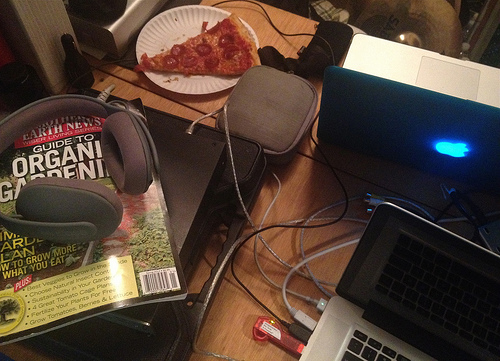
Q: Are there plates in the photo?
A: Yes, there is a plate.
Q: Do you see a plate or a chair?
A: Yes, there is a plate.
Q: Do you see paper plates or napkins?
A: Yes, there is a paper plate.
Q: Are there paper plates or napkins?
A: Yes, there is a paper plate.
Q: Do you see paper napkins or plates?
A: Yes, there is a paper plate.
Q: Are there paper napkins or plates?
A: Yes, there is a paper plate.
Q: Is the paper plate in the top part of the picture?
A: Yes, the plate is in the top of the image.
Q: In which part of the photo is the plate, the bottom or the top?
A: The plate is in the top of the image.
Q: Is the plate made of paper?
A: Yes, the plate is made of paper.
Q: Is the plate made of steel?
A: No, the plate is made of paper.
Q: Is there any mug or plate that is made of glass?
A: No, there is a plate but it is made of paper.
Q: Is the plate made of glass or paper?
A: The plate is made of paper.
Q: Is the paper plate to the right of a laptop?
A: No, the plate is to the left of a laptop.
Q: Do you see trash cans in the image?
A: No, there are no trash cans.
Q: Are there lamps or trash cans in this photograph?
A: No, there are no trash cans or lamps.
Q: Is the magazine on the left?
A: Yes, the magazine is on the left of the image.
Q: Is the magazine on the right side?
A: No, the magazine is on the left of the image.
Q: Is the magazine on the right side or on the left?
A: The magazine is on the left of the image.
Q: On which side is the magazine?
A: The magazine is on the left of the image.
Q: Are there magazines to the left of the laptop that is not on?
A: Yes, there is a magazine to the left of the laptop computer.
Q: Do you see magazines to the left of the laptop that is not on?
A: Yes, there is a magazine to the left of the laptop computer.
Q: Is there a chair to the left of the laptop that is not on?
A: No, there is a magazine to the left of the laptop.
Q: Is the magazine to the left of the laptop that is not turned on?
A: Yes, the magazine is to the left of the laptop.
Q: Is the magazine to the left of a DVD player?
A: No, the magazine is to the left of the laptop.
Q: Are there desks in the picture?
A: Yes, there is a desk.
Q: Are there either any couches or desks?
A: Yes, there is a desk.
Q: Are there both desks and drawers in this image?
A: No, there is a desk but no drawers.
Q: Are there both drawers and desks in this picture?
A: No, there is a desk but no drawers.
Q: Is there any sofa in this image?
A: No, there are no sofas.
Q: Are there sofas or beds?
A: No, there are no sofas or beds.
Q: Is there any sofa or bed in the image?
A: No, there are no sofas or beds.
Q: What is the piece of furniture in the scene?
A: The piece of furniture is a desk.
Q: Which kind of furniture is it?
A: The piece of furniture is a desk.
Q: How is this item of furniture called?
A: This is a desk.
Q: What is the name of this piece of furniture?
A: This is a desk.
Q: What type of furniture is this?
A: This is a desk.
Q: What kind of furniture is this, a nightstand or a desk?
A: This is a desk.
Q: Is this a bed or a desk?
A: This is a desk.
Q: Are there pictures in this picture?
A: No, there are no pictures.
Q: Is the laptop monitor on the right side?
A: Yes, the monitor is on the right of the image.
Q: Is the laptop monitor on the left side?
A: No, the monitor is on the right of the image.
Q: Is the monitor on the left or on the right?
A: The monitor is on the right of the image.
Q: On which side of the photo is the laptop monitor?
A: The monitor is on the right of the image.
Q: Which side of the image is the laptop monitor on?
A: The monitor is on the right of the image.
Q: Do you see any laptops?
A: Yes, there is a laptop.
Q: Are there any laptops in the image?
A: Yes, there is a laptop.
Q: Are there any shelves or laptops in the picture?
A: Yes, there is a laptop.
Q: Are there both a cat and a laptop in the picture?
A: No, there is a laptop but no cats.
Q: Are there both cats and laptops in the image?
A: No, there is a laptop but no cats.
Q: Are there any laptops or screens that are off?
A: Yes, the laptop is off.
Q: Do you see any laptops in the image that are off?
A: Yes, there is a laptop that is off.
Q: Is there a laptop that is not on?
A: Yes, there is a laptop that is off.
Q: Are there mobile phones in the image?
A: No, there are no mobile phones.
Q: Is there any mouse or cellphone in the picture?
A: No, there are no cell phones or computer mice.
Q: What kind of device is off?
A: The device is a laptop.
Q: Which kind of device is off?
A: The device is a laptop.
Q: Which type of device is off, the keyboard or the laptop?
A: The laptop is off.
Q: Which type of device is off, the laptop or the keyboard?
A: The laptop is off.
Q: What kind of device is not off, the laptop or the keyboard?
A: The keyboard is not off.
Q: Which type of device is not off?
A: The device is a keyboard.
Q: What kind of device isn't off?
A: The device is a keyboard.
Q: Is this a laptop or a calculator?
A: This is a laptop.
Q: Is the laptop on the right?
A: Yes, the laptop is on the right of the image.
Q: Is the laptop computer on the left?
A: No, the laptop computer is on the right of the image.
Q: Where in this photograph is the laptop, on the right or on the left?
A: The laptop is on the right of the image.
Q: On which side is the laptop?
A: The laptop is on the right of the image.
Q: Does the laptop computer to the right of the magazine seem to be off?
A: Yes, the laptop computer is off.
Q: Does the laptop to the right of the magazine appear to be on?
A: No, the laptop is off.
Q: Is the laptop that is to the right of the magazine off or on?
A: The laptop is off.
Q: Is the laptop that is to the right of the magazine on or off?
A: The laptop is off.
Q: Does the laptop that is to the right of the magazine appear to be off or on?
A: The laptop is off.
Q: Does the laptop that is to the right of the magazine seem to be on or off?
A: The laptop is off.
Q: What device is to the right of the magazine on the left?
A: The device is a laptop.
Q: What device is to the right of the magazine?
A: The device is a laptop.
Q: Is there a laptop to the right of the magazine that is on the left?
A: Yes, there is a laptop to the right of the magazine.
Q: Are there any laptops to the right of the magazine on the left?
A: Yes, there is a laptop to the right of the magazine.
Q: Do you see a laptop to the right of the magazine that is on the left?
A: Yes, there is a laptop to the right of the magazine.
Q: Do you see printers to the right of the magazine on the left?
A: No, there is a laptop to the right of the magazine.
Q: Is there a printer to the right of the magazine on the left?
A: No, there is a laptop to the right of the magazine.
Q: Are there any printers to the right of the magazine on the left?
A: No, there is a laptop to the right of the magazine.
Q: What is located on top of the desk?
A: The laptop computer is on top of the desk.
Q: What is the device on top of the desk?
A: The device is a laptop.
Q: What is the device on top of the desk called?
A: The device is a laptop.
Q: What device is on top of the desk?
A: The device is a laptop.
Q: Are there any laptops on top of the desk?
A: Yes, there is a laptop on top of the desk.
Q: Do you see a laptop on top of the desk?
A: Yes, there is a laptop on top of the desk.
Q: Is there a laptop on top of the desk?
A: Yes, there is a laptop on top of the desk.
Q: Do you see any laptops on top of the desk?
A: Yes, there is a laptop on top of the desk.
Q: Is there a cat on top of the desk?
A: No, there is a laptop on top of the desk.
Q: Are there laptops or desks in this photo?
A: Yes, there is a laptop.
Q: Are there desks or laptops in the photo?
A: Yes, there is a laptop.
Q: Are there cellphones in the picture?
A: No, there are no cellphones.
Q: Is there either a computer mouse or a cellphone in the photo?
A: No, there are no cell phones or computer mice.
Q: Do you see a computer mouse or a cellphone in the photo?
A: No, there are no cell phones or computer mice.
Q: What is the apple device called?
A: The device is a laptop.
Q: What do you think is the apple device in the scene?
A: The device is a laptop.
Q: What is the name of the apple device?
A: The device is a laptop.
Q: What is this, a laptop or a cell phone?
A: This is a laptop.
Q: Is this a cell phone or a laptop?
A: This is a laptop.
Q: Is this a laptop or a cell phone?
A: This is a laptop.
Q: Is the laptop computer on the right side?
A: Yes, the laptop computer is on the right of the image.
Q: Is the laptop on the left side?
A: No, the laptop is on the right of the image.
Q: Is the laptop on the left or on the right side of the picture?
A: The laptop is on the right of the image.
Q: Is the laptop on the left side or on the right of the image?
A: The laptop is on the right of the image.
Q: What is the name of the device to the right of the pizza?
A: The device is a laptop.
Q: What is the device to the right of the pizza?
A: The device is a laptop.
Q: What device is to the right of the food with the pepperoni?
A: The device is a laptop.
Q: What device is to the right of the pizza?
A: The device is a laptop.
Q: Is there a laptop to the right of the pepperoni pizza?
A: Yes, there is a laptop to the right of the pizza.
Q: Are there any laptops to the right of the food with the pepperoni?
A: Yes, there is a laptop to the right of the pizza.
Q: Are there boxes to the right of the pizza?
A: No, there is a laptop to the right of the pizza.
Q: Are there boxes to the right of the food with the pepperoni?
A: No, there is a laptop to the right of the pizza.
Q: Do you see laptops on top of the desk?
A: Yes, there is a laptop on top of the desk.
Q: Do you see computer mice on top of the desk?
A: No, there is a laptop on top of the desk.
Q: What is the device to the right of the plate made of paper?
A: The device is a laptop.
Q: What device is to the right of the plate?
A: The device is a laptop.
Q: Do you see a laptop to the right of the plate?
A: Yes, there is a laptop to the right of the plate.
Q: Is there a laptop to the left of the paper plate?
A: No, the laptop is to the right of the plate.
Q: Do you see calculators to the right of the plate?
A: No, there is a laptop to the right of the plate.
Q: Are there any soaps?
A: No, there are no soaps.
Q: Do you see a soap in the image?
A: No, there are no soaps.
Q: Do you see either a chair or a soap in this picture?
A: No, there are no soaps or chairs.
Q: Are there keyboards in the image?
A: Yes, there is a keyboard.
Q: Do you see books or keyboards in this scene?
A: Yes, there is a keyboard.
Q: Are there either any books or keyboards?
A: Yes, there is a keyboard.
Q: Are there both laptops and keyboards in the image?
A: Yes, there are both a keyboard and a laptop.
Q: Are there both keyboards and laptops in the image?
A: Yes, there are both a keyboard and a laptop.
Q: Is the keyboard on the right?
A: Yes, the keyboard is on the right of the image.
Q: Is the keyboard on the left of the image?
A: No, the keyboard is on the right of the image.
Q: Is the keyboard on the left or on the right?
A: The keyboard is on the right of the image.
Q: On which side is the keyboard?
A: The keyboard is on the right of the image.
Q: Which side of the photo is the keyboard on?
A: The keyboard is on the right of the image.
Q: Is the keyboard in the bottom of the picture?
A: Yes, the keyboard is in the bottom of the image.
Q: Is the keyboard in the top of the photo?
A: No, the keyboard is in the bottom of the image.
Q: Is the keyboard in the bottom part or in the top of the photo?
A: The keyboard is in the bottom of the image.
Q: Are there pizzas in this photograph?
A: Yes, there is a pizza.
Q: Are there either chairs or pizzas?
A: Yes, there is a pizza.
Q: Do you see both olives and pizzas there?
A: No, there is a pizza but no olives.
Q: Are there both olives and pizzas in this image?
A: No, there is a pizza but no olives.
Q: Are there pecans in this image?
A: No, there are no pecans.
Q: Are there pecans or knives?
A: No, there are no pecans or knives.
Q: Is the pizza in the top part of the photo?
A: Yes, the pizza is in the top of the image.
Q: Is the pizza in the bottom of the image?
A: No, the pizza is in the top of the image.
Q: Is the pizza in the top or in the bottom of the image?
A: The pizza is in the top of the image.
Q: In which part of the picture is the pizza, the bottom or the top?
A: The pizza is in the top of the image.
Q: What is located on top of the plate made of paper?
A: The pizza is on top of the plate.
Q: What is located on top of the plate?
A: The pizza is on top of the plate.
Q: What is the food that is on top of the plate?
A: The food is a pizza.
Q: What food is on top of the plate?
A: The food is a pizza.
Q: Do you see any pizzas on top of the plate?
A: Yes, there is a pizza on top of the plate.